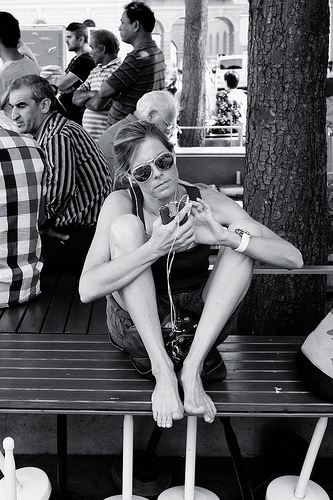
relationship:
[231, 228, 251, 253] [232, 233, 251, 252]
watch with white band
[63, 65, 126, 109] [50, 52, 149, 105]
men with folded arms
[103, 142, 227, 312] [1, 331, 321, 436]
woman sitting on bench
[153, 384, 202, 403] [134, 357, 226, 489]
veins on foot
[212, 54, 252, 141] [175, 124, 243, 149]
stand with base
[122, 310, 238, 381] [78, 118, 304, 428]
purse of woman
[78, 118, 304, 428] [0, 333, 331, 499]
woman on bench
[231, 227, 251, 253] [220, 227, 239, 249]
watch on wrist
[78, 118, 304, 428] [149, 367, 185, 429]
woman on foot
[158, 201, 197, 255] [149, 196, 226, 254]
cell phone on hands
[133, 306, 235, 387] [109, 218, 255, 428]
purse under legs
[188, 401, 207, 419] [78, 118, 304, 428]
toe on woman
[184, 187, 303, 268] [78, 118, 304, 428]
arm on woman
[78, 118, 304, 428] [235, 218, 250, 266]
woman wearing watch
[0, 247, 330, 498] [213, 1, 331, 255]
bench around tree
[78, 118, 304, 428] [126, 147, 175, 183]
woman wearing sunglasses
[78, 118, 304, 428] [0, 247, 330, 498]
woman sitting on bench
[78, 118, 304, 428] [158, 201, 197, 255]
woman using cell phone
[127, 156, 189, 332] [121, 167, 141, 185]
earphones in ear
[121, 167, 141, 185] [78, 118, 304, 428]
ear on woman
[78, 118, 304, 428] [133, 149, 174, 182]
woman wearing sunglasses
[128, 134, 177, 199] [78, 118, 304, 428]
face on woman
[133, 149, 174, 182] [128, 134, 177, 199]
sunglasses on face